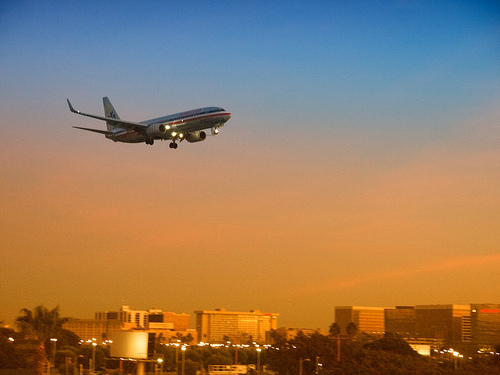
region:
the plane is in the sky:
[35, 69, 257, 171]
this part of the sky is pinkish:
[2, 137, 494, 322]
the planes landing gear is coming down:
[168, 135, 181, 155]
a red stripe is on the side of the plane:
[179, 112, 238, 122]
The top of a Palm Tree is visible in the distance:
[13, 305, 76, 371]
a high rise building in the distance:
[197, 309, 277, 351]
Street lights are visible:
[178, 344, 190, 371]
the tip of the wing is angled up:
[60, 94, 88, 122]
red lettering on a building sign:
[478, 309, 496, 318]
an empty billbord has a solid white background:
[108, 329, 158, 361]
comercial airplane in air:
[51, 73, 253, 161]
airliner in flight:
[49, 78, 265, 218]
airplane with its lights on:
[38, 77, 270, 160]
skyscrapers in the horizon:
[66, 301, 498, 333]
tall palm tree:
[8, 297, 90, 372]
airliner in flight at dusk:
[19, 58, 274, 159]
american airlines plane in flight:
[50, 88, 259, 159]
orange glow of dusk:
[28, 140, 495, 325]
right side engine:
[144, 121, 172, 141]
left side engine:
[189, 129, 215, 150]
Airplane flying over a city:
[65, 95, 230, 157]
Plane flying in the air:
[64, 92, 232, 148]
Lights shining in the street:
[2, 330, 294, 362]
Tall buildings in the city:
[63, 305, 275, 362]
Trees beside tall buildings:
[25, 305, 482, 374]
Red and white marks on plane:
[171, 109, 232, 129]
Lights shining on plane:
[161, 120, 228, 144]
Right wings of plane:
[65, 98, 144, 143]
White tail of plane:
[104, 97, 122, 129]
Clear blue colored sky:
[0, 8, 498, 122]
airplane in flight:
[59, 86, 237, 147]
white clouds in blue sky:
[17, 14, 61, 52]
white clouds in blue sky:
[264, 110, 290, 177]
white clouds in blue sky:
[271, 105, 323, 187]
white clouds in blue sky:
[340, 33, 363, 85]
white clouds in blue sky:
[409, 22, 448, 133]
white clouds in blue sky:
[420, 80, 456, 150]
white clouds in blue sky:
[117, 41, 168, 82]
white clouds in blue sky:
[1, 79, 43, 143]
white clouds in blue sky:
[31, 133, 70, 191]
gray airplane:
[34, 83, 234, 154]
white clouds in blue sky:
[323, 23, 380, 93]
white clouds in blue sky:
[316, 170, 353, 215]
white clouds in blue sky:
[409, 113, 440, 200]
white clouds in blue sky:
[320, 125, 348, 186]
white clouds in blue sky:
[70, 227, 175, 262]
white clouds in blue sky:
[241, 203, 292, 253]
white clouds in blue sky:
[76, 17, 171, 59]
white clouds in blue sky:
[256, 21, 314, 79]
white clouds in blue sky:
[23, 123, 67, 170]